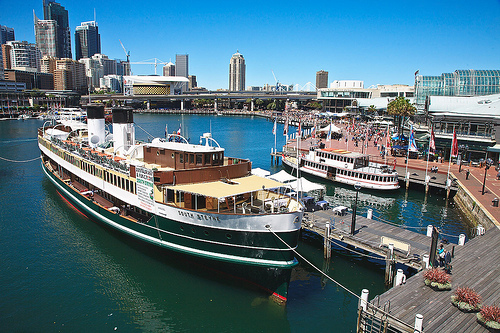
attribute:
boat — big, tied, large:
[39, 105, 299, 276]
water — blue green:
[2, 114, 477, 332]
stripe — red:
[271, 292, 289, 302]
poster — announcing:
[134, 165, 155, 215]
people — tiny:
[436, 244, 452, 276]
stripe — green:
[41, 160, 295, 268]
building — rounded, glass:
[415, 71, 499, 108]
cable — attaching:
[266, 224, 360, 299]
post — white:
[358, 289, 368, 311]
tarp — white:
[253, 166, 324, 192]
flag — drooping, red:
[449, 125, 459, 157]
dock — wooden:
[303, 205, 499, 329]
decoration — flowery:
[53, 133, 127, 170]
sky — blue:
[2, 1, 499, 88]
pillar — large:
[112, 106, 134, 155]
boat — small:
[282, 146, 401, 199]